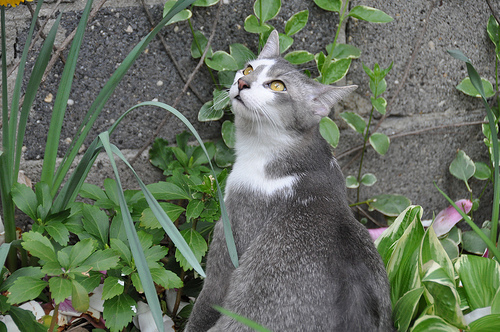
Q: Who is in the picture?
A: Cat.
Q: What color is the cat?
A: Grey and white.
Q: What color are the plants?
A: Green.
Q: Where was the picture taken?
A: Outside of building.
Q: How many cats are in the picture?
A: One.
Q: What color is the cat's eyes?
A: Yellow.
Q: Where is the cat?
A: In a flower bed.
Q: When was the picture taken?
A: During the day.